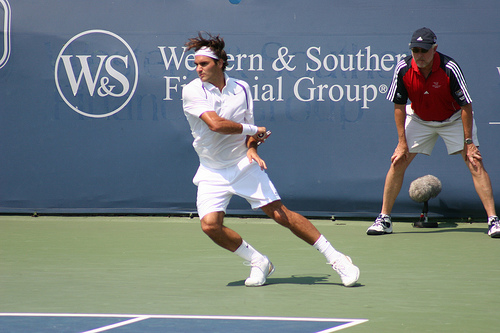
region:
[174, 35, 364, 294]
man playing tennis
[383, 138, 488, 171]
hands on the knees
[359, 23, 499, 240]
man standing on the back of the court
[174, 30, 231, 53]
hair is blowing in the wind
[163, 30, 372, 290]
tennis player is leaning to the side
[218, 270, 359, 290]
shadow from the tennis player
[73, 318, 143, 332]
white line on the court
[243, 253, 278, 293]
heel lifted off the ground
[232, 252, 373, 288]
a pair of white tennis shoes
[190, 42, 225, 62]
thick white band around the head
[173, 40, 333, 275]
man is kicking a ball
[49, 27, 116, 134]
words are witten in white color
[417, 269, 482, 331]
floor is green in color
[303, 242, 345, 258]
socks are white in color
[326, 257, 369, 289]
shoes are white in color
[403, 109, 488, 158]
short is grey in color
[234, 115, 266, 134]
hand scarf is white in color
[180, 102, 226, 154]
t shirt is white in c9olor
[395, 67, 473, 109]
t shirt is red in color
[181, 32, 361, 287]
A man with crazy brown hair in mostly white.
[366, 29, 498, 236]
A man in a red, white and black shirt leaning down.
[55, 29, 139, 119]
A white circle with a W&S inside.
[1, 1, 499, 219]
A blue back wall with writing on it.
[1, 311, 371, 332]
White lines that outline a blue tennis court.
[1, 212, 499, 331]
A green tennis court area.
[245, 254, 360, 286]
Pure white tennis shoes on a tennis player.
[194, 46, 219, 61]
A white headband on a tennis player.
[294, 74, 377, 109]
The white word Group.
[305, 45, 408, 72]
The word Southern on a wall.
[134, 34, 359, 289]
Roger Federer on court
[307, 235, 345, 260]
tall white sock on player's feet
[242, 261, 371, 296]
new pair of white sneakers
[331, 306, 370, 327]
white edge on blue court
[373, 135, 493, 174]
man's hand on his knee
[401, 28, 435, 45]
small white logo on top of cap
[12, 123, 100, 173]
blue color on the wall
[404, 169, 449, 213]
microphone on the court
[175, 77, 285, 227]
white tennis clothes on player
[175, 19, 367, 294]
tennis phenom Roger Federer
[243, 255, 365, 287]
white tennis shoes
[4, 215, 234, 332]
green and blue court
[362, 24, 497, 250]
ball boy at the ready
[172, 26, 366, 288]
Roger about to hit the ball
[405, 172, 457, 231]
grey fuzzy thing on the court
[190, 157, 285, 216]
all white tennis shorts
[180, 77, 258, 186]
all white tennis polo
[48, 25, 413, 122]
tennis tourney sponsor ad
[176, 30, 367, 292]
tennis pro Roger Federer